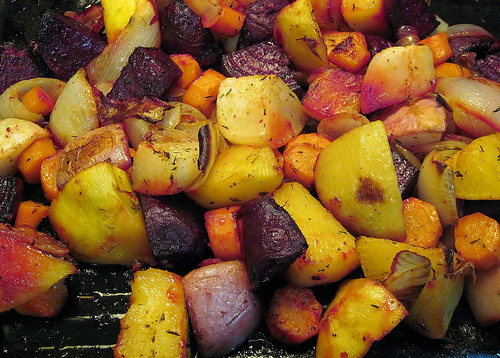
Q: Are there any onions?
A: Yes, there is an onion.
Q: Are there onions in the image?
A: Yes, there is an onion.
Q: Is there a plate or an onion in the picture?
A: Yes, there is an onion.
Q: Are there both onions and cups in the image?
A: No, there is an onion but no cups.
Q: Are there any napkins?
A: No, there are no napkins.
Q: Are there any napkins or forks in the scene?
A: No, there are no napkins or forks.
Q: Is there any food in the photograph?
A: Yes, there is food.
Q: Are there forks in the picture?
A: No, there are no forks.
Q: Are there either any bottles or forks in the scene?
A: No, there are no forks or bottles.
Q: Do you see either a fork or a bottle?
A: No, there are no forks or bottles.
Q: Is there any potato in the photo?
A: Yes, there is a potato.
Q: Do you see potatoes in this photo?
A: Yes, there is a potato.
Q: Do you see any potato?
A: Yes, there is a potato.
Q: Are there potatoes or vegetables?
A: Yes, there is a potato.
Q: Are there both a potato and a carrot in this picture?
A: Yes, there are both a potato and a carrot.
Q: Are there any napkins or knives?
A: No, there are no napkins or knives.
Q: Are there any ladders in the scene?
A: No, there are no ladders.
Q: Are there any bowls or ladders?
A: No, there are no ladders or bowls.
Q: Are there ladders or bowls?
A: No, there are no ladders or bowls.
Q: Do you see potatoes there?
A: Yes, there is a potato.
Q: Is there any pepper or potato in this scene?
A: Yes, there is a potato.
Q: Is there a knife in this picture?
A: No, there are no knives.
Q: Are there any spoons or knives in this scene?
A: No, there are no knives or spoons.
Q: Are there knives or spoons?
A: No, there are no knives or spoons.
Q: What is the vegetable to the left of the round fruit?
A: The vegetable is a potato.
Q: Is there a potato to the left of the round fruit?
A: Yes, there is a potato to the left of the fruit.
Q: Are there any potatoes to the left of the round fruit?
A: Yes, there is a potato to the left of the fruit.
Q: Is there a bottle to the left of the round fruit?
A: No, there is a potato to the left of the fruit.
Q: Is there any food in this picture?
A: Yes, there is food.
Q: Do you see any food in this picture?
A: Yes, there is food.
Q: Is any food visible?
A: Yes, there is food.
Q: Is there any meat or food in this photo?
A: Yes, there is food.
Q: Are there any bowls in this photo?
A: No, there are no bowls.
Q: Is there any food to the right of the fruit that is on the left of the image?
A: Yes, there is food to the right of the fruit.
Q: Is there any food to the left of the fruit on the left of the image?
A: No, the food is to the right of the fruit.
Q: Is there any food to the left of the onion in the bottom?
A: Yes, there is food to the left of the onion.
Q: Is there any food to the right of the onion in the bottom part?
A: No, the food is to the left of the onion.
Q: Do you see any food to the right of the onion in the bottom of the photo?
A: No, the food is to the left of the onion.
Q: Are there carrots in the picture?
A: Yes, there is a carrot.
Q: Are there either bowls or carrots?
A: Yes, there is a carrot.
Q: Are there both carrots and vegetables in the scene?
A: Yes, there are both a carrot and a vegetable.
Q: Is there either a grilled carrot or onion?
A: Yes, there is a grilled carrot.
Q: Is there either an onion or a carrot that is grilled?
A: Yes, the carrot is grilled.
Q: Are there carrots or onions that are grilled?
A: Yes, the carrot is grilled.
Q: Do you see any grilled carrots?
A: Yes, there is a grilled carrot.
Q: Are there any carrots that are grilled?
A: Yes, there is a carrot that is grilled.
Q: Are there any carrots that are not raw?
A: Yes, there is a grilled carrot.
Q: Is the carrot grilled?
A: Yes, the carrot is grilled.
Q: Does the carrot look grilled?
A: Yes, the carrot is grilled.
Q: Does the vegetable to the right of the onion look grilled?
A: Yes, the carrot is grilled.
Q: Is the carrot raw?
A: No, the carrot is grilled.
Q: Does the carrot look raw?
A: No, the carrot is grilled.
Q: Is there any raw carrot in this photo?
A: No, there is a carrot but it is grilled.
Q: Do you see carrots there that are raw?
A: No, there is a carrot but it is grilled.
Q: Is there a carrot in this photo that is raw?
A: No, there is a carrot but it is grilled.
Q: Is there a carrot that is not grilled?
A: No, there is a carrot but it is grilled.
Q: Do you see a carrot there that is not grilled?
A: No, there is a carrot but it is grilled.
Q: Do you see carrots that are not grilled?
A: No, there is a carrot but it is grilled.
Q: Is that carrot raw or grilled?
A: The carrot is grilled.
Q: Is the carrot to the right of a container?
A: No, the carrot is to the right of the onion.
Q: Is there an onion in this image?
A: Yes, there are onions.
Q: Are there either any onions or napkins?
A: Yes, there are onions.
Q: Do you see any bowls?
A: No, there are no bowls.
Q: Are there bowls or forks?
A: No, there are no bowls or forks.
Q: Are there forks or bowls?
A: No, there are no bowls or forks.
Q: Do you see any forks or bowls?
A: No, there are no bowls or forks.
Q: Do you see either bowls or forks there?
A: No, there are no bowls or forks.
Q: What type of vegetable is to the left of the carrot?
A: The vegetables are onions.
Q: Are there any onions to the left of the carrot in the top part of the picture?
A: Yes, there are onions to the left of the carrot.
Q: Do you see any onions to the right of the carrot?
A: No, the onions are to the left of the carrot.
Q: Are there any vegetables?
A: Yes, there are vegetables.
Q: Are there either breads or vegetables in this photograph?
A: Yes, there are vegetables.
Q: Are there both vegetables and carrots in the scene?
A: Yes, there are both vegetables and a carrot.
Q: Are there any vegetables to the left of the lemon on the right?
A: Yes, there are vegetables to the left of the lemon.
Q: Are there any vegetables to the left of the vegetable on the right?
A: Yes, there are vegetables to the left of the lemon.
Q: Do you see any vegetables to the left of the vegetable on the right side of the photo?
A: Yes, there are vegetables to the left of the lemon.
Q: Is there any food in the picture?
A: Yes, there is food.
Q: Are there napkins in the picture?
A: No, there are no napkins.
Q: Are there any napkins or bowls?
A: No, there are no napkins or bowls.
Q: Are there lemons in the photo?
A: Yes, there is a lemon.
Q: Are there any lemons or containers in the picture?
A: Yes, there is a lemon.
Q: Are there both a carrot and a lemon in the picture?
A: Yes, there are both a lemon and a carrot.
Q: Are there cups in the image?
A: No, there are no cups.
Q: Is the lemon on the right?
A: Yes, the lemon is on the right of the image.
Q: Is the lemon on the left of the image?
A: No, the lemon is on the right of the image.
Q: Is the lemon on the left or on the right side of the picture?
A: The lemon is on the right of the image.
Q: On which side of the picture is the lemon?
A: The lemon is on the right of the image.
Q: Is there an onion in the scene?
A: Yes, there is an onion.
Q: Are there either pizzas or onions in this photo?
A: Yes, there is an onion.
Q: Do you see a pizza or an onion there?
A: Yes, there is an onion.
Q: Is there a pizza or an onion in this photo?
A: Yes, there is an onion.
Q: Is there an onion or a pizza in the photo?
A: Yes, there is an onion.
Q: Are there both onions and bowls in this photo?
A: No, there is an onion but no bowls.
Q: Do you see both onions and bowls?
A: No, there is an onion but no bowls.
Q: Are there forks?
A: No, there are no forks.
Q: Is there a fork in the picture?
A: No, there are no forks.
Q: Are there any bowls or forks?
A: No, there are no forks or bowls.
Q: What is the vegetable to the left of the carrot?
A: The vegetable is an onion.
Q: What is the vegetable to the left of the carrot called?
A: The vegetable is an onion.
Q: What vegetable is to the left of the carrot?
A: The vegetable is an onion.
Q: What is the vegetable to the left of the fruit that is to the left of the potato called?
A: The vegetable is an onion.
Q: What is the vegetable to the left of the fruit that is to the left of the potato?
A: The vegetable is an onion.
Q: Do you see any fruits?
A: Yes, there is a fruit.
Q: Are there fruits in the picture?
A: Yes, there is a fruit.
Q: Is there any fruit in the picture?
A: Yes, there is a fruit.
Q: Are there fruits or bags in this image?
A: Yes, there is a fruit.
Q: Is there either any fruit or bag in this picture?
A: Yes, there is a fruit.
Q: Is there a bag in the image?
A: No, there are no bags.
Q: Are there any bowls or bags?
A: No, there are no bags or bowls.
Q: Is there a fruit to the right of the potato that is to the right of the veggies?
A: Yes, there is a fruit to the right of the potato.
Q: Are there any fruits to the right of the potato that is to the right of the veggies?
A: Yes, there is a fruit to the right of the potato.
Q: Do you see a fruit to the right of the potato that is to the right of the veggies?
A: Yes, there is a fruit to the right of the potato.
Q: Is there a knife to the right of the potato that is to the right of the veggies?
A: No, there is a fruit to the right of the potato.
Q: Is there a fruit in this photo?
A: Yes, there is a fruit.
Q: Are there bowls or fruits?
A: Yes, there is a fruit.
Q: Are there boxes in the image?
A: No, there are no boxes.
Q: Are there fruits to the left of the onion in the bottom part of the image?
A: Yes, there is a fruit to the left of the onion.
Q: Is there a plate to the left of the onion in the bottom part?
A: No, there is a fruit to the left of the onion.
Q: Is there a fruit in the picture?
A: Yes, there is a fruit.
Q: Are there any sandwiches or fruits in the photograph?
A: Yes, there is a fruit.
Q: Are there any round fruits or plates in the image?
A: Yes, there is a round fruit.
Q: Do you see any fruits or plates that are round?
A: Yes, the fruit is round.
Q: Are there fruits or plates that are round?
A: Yes, the fruit is round.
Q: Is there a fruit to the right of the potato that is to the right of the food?
A: Yes, there is a fruit to the right of the potato.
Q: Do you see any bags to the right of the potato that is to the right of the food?
A: No, there is a fruit to the right of the potato.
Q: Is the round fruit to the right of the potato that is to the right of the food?
A: Yes, the fruit is to the right of the potato.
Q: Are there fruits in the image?
A: Yes, there is a fruit.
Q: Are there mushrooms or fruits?
A: Yes, there is a fruit.